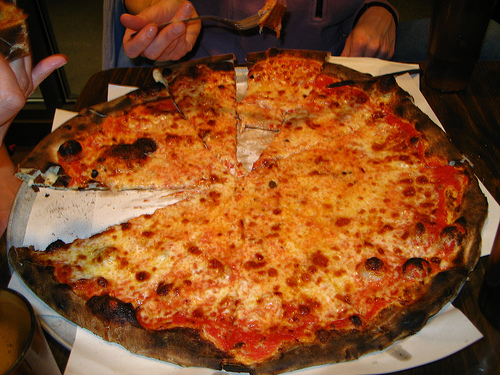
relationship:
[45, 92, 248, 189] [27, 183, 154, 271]
pizza on pan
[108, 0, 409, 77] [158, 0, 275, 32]
man holding fork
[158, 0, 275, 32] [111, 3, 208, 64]
fork in hand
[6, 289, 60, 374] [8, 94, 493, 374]
glass on table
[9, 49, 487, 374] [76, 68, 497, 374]
pizza on table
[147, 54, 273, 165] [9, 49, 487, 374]
slice of pizza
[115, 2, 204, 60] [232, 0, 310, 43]
hand of man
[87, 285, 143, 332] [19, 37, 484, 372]
spot on crust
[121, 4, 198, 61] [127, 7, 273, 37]
fingers on fork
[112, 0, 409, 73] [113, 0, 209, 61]
man has hand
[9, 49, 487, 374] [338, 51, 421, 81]
pizza on paper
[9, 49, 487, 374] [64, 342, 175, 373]
pizza on paper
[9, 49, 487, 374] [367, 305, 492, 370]
pizza on paper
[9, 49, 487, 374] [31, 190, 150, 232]
pizza on paper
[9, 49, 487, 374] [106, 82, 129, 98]
pizza on paper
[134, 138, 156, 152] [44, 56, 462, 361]
spot on cheese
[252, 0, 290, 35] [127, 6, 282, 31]
food on fork